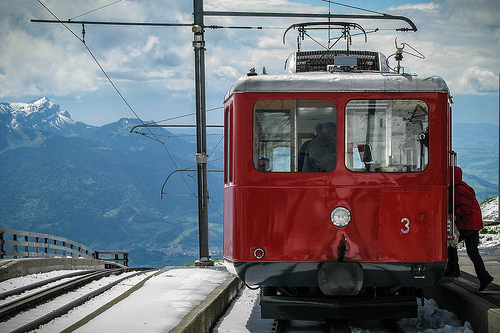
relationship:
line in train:
[84, 45, 149, 122] [215, 69, 464, 320]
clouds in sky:
[3, 0, 498, 91] [93, 22, 298, 73]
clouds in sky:
[3, 0, 498, 91] [2, 2, 495, 125]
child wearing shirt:
[447, 163, 494, 290] [451, 181, 485, 238]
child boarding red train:
[447, 163, 494, 290] [220, 49, 457, 331]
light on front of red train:
[328, 207, 350, 227] [220, 22, 461, 278]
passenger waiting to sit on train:
[300, 113, 331, 171] [235, 70, 470, 300]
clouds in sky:
[3, 3, 498, 91] [3, 1, 498, 161]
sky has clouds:
[4, 3, 498, 141] [66, 13, 228, 88]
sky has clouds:
[0, 0, 498, 140] [3, 3, 498, 91]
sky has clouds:
[0, 0, 498, 140] [123, 37, 165, 68]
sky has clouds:
[0, 0, 498, 140] [9, 30, 191, 112]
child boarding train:
[447, 166, 495, 293] [223, 55, 462, 300]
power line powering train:
[192, 0, 215, 268] [226, 70, 451, 307]